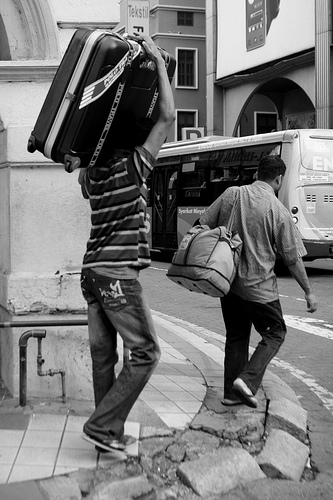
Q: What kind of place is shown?
A: It is a sidewalk.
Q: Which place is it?
A: It is a sidewalk.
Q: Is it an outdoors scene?
A: Yes, it is outdoors.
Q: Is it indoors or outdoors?
A: It is outdoors.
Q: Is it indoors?
A: No, it is outdoors.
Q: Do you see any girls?
A: No, there are no girls.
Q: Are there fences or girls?
A: No, there are no girls or fences.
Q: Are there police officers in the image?
A: No, there are no police officers.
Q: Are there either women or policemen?
A: No, there are no policemen or women.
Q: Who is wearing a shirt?
A: The man is wearing a shirt.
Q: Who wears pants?
A: The man wears pants.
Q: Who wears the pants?
A: The man wears pants.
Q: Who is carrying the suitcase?
A: The man is carrying the suitcase.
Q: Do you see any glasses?
A: No, there are no glasses.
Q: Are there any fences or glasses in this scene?
A: No, there are no glasses or fences.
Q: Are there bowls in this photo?
A: No, there are no bowls.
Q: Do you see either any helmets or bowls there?
A: No, there are no bowls or helmets.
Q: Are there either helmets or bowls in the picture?
A: No, there are no bowls or helmets.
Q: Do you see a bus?
A: Yes, there is a bus.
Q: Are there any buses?
A: Yes, there is a bus.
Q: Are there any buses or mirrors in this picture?
A: Yes, there is a bus.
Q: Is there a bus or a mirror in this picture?
A: Yes, there is a bus.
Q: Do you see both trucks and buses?
A: No, there is a bus but no trucks.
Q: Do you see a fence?
A: No, there are no fences.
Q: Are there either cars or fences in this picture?
A: No, there are no fences or cars.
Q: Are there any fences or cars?
A: No, there are no fences or cars.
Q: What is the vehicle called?
A: The vehicle is a bus.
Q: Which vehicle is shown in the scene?
A: The vehicle is a bus.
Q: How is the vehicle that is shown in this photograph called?
A: The vehicle is a bus.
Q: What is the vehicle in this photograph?
A: The vehicle is a bus.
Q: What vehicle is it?
A: The vehicle is a bus.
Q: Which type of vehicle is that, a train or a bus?
A: This is a bus.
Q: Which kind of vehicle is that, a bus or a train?
A: This is a bus.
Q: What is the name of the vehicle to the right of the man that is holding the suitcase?
A: The vehicle is a bus.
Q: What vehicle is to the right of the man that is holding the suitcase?
A: The vehicle is a bus.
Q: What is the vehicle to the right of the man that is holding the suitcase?
A: The vehicle is a bus.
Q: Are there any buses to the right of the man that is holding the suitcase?
A: Yes, there is a bus to the right of the man.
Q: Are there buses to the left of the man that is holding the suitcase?
A: No, the bus is to the right of the man.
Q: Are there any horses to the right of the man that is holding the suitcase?
A: No, there is a bus to the right of the man.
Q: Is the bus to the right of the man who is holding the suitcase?
A: Yes, the bus is to the right of the man.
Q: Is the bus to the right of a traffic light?
A: No, the bus is to the right of the man.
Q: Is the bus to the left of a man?
A: No, the bus is to the right of a man.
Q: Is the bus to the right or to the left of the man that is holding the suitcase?
A: The bus is to the right of the man.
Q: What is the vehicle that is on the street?
A: The vehicle is a bus.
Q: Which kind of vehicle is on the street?
A: The vehicle is a bus.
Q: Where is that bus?
A: The bus is on the street.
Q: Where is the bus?
A: The bus is on the street.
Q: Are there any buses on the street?
A: Yes, there is a bus on the street.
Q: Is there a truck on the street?
A: No, there is a bus on the street.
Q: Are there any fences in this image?
A: No, there are no fences.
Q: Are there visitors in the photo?
A: No, there are no visitors.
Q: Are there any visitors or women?
A: No, there are no visitors or women.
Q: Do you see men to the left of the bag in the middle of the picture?
A: Yes, there is a man to the left of the bag.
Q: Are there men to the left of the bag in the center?
A: Yes, there is a man to the left of the bag.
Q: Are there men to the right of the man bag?
A: No, the man is to the left of the bag.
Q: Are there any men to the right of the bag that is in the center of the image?
A: No, the man is to the left of the bag.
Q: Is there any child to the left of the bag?
A: No, there is a man to the left of the bag.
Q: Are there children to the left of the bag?
A: No, there is a man to the left of the bag.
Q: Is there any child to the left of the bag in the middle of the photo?
A: No, there is a man to the left of the bag.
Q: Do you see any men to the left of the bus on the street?
A: Yes, there is a man to the left of the bus.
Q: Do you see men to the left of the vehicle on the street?
A: Yes, there is a man to the left of the bus.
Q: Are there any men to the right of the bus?
A: No, the man is to the left of the bus.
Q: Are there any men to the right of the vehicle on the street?
A: No, the man is to the left of the bus.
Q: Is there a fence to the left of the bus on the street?
A: No, there is a man to the left of the bus.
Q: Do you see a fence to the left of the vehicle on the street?
A: No, there is a man to the left of the bus.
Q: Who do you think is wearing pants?
A: The man is wearing pants.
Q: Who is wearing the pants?
A: The man is wearing pants.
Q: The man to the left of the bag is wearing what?
A: The man is wearing trousers.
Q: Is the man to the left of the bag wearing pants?
A: Yes, the man is wearing pants.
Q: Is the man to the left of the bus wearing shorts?
A: No, the man is wearing pants.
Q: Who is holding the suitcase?
A: The man is holding the suitcase.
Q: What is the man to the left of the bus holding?
A: The man is holding the suitcase.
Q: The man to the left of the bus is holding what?
A: The man is holding the suitcase.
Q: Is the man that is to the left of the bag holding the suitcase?
A: Yes, the man is holding the suitcase.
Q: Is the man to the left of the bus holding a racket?
A: No, the man is holding the suitcase.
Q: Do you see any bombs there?
A: No, there are no bombs.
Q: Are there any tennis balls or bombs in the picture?
A: No, there are no bombs or tennis balls.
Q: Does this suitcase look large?
A: Yes, the suitcase is large.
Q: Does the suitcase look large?
A: Yes, the suitcase is large.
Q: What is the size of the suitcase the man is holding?
A: The suitcase is large.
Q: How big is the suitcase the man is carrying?
A: The suitcase is large.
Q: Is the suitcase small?
A: No, the suitcase is large.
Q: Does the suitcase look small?
A: No, the suitcase is large.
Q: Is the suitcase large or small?
A: The suitcase is large.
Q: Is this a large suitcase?
A: Yes, this is a large suitcase.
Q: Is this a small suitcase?
A: No, this is a large suitcase.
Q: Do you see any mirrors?
A: No, there are no mirrors.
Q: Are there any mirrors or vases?
A: No, there are no mirrors or vases.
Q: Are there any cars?
A: No, there are no cars.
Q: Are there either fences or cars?
A: No, there are no cars or fences.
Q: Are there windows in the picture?
A: Yes, there is a window.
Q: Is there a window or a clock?
A: Yes, there is a window.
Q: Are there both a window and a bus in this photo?
A: Yes, there are both a window and a bus.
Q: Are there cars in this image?
A: No, there are no cars.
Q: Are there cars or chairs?
A: No, there are no cars or chairs.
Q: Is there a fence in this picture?
A: No, there are no fences.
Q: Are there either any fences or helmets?
A: No, there are no fences or helmets.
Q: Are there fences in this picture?
A: No, there are no fences.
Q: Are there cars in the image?
A: No, there are no cars.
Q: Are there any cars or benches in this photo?
A: No, there are no cars or benches.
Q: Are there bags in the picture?
A: Yes, there is a bag.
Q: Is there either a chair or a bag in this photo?
A: Yes, there is a bag.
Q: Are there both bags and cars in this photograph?
A: No, there is a bag but no cars.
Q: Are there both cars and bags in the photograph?
A: No, there is a bag but no cars.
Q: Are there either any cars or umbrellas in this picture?
A: No, there are no cars or umbrellas.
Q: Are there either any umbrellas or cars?
A: No, there are no cars or umbrellas.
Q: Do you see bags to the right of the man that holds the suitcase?
A: Yes, there is a bag to the right of the man.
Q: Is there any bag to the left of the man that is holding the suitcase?
A: No, the bag is to the right of the man.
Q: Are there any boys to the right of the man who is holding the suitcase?
A: No, there is a bag to the right of the man.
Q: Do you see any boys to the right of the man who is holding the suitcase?
A: No, there is a bag to the right of the man.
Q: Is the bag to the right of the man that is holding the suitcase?
A: Yes, the bag is to the right of the man.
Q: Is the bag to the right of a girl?
A: No, the bag is to the right of the man.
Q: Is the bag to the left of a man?
A: No, the bag is to the right of a man.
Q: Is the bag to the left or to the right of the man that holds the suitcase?
A: The bag is to the right of the man.